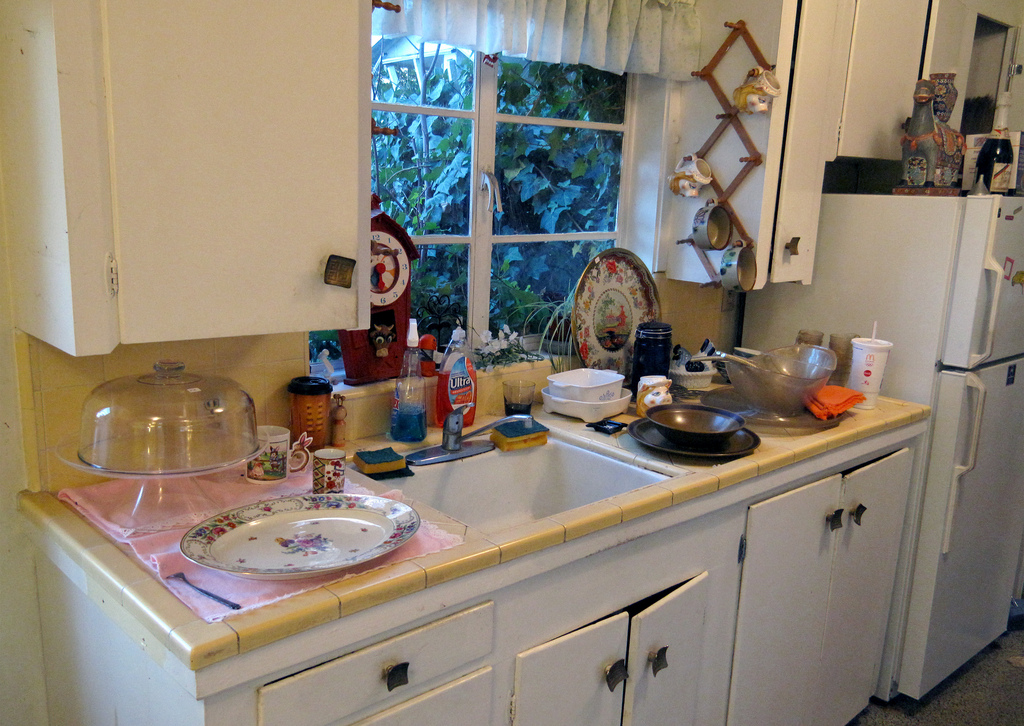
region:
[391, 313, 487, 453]
several bottles of dish washing liquid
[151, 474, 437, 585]
a ceramic china or plate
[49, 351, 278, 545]
a glass cake tray with cover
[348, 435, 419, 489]
sponge foam for washing plates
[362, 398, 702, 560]
a rectangular kitchen sink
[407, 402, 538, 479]
faucet for a kitchen sink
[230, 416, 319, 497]
a coffee mug on a pink cloth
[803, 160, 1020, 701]
a white fridge next to the kitchen sink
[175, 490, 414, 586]
A large plate on counter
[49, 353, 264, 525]
Clear cake holder on counter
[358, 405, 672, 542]
Kitchen sink in counter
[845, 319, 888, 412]
Soda cup on counter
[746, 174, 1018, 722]
White refridgerator next to counter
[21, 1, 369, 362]
White cabinet above counter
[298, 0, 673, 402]
Window above sink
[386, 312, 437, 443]
Window spray next to sink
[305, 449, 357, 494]
Tea cup next to plate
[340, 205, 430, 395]
Clock on window sill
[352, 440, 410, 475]
Sponge next to the faucet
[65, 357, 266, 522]
Glass cake stand under the cabinet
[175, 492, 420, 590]
Floral plate sitting on a pink towel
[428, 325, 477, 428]
Bottle of dish soap behind faucet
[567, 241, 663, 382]
Large round plate leaning on a window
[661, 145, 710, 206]
Mug hanging from wooden rack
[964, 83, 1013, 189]
Bottle sitting on top of a fridge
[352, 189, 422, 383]
Wooden clock sitting in front of the window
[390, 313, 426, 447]
Bottle of Windex next to the dish soap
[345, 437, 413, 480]
Cleaning sponge by the sink.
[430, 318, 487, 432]
Orange colored dish soap.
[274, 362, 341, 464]
Coffee cup by the window.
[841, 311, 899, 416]
White McDonald's cup on counter.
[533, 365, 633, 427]
White dishes by the sink.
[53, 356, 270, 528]
A glass cake dish.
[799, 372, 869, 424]
Orange towel by a bowl.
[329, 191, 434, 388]
A wooden clock by the window.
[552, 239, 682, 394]
Decorative plate by the window.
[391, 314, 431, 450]
Plastic bottle of cleaner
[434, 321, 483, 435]
Plastic bottle of dish soap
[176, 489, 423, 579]
White plate with colored pattern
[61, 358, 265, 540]
Glass cake plate with cover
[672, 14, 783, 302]
Wooden wall cup holder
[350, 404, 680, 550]
White sink with silver faucet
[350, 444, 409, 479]
Green and yellow dish sponge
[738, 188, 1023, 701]
White refrigerator next to cabinets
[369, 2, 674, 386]
Window with white curtain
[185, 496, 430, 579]
A white plate on the counter.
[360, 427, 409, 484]
A blue sponge on top of sink.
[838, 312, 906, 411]
A white plastic cup on the counter.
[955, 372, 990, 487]
White handle to the refrigerator.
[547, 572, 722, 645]
The cabinet door is slightly opened.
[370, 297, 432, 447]
A plastic bottle on the sink counter.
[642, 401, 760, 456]
A gray bowl on the saucer.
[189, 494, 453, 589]
A white plate on the counter.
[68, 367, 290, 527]
A cake covering on the counter.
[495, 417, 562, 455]
A sponge sitting on the sink.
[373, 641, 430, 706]
A knob on the kitchen drawer.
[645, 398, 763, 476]
A bowl and saucer on the counter.